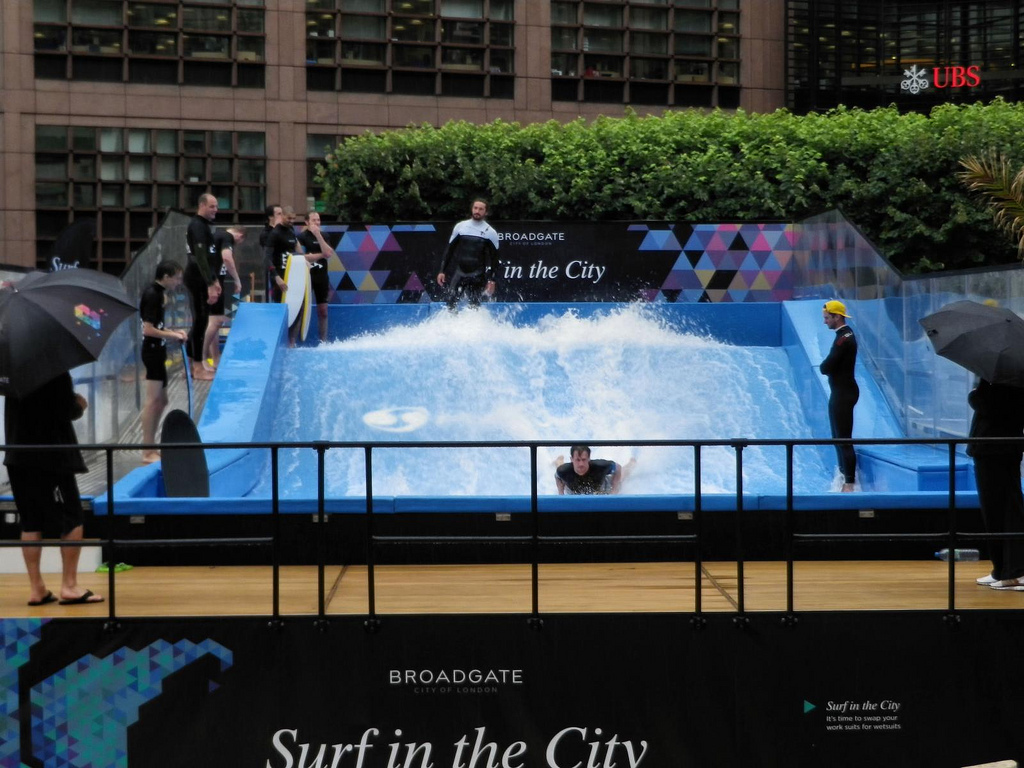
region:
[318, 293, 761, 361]
wavy water in the enclosure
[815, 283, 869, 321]
yellow cap on man's head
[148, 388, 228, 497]
skateboard in the water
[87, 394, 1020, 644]
black railing in front of pool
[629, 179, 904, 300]
diamond pattern behind water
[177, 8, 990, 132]
huge building behind the poool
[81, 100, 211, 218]
white blinds in the building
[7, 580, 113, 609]
Person wearing sandals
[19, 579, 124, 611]
Person is wearing sandals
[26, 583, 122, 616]
Person wearing black sandals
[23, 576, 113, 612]
Person is wearing black sandals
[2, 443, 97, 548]
Person wearing shorts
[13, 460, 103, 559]
Person is wearing shorts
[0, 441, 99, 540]
Person wearing black shorts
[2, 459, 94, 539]
Person is wearing black shorts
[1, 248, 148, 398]
Person carrying a black umbrella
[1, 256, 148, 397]
Person is carrying a black umbrella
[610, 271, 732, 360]
A person eating a orange.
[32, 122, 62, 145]
glass window pane behind the surfer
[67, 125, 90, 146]
glass window pane behind the surfer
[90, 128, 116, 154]
glass window pane behind the surfer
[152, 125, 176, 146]
glass window pane behind the surfer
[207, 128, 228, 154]
glass window pane behind the surfer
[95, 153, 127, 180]
glass window pane behind the surfer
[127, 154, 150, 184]
glass window pane behind the surfer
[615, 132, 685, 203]
green leaves on the tree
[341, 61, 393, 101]
A window on a building.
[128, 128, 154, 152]
A window on a building.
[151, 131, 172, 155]
A window on a building.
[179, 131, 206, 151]
A window on a building.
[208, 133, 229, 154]
A window on a building.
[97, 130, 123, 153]
A window on a building.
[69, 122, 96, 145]
A window on a building.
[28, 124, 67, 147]
A window on a building.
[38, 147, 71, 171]
A window on a building.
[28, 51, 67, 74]
A window on a building.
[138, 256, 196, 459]
a person is standing up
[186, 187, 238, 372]
a person is standing up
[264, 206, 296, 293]
a person is standing up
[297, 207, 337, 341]
a person is standing up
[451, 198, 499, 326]
a person is standing up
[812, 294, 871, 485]
a person is standing up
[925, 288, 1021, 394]
a large open umbrella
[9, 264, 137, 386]
a large open umbrella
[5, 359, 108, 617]
a person is standing up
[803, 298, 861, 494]
person by the artificial wave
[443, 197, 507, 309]
person by the artificial wave